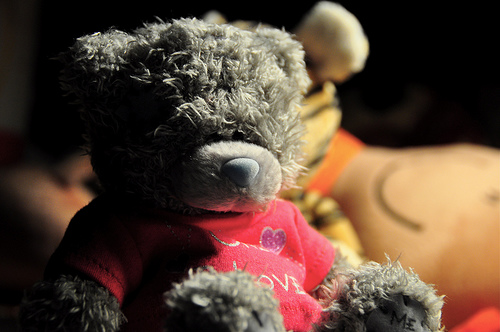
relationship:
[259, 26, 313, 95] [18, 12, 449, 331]
ear of bear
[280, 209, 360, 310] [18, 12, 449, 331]
arm of bear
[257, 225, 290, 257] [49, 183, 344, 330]
heart on shirt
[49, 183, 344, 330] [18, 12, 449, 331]
shirt of bear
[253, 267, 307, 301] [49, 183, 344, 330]
ove on shirt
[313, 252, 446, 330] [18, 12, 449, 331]
foot of bear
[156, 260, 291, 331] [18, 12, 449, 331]
foot of bear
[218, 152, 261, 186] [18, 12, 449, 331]
nose of bear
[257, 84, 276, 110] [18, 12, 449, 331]
eyes of bear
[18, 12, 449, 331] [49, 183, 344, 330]
bear wearing shirt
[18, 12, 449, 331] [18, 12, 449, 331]
bear behind bear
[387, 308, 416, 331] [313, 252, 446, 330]
me on foot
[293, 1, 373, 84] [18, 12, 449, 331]
ear behind bear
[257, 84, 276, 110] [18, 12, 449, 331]
eyes on bear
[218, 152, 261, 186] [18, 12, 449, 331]
nose on bear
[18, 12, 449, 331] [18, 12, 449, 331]
bear in front of bear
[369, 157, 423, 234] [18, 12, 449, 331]
smile on bear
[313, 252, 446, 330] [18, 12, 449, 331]
foot on bear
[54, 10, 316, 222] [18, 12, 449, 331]
head of bear